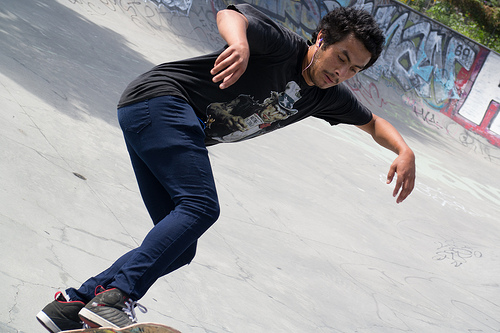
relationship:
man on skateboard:
[38, 4, 416, 332] [62, 322, 184, 331]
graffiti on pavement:
[154, 0, 499, 146] [3, 0, 496, 332]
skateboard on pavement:
[62, 322, 184, 331] [3, 0, 496, 332]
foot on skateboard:
[36, 286, 85, 332] [62, 322, 184, 331]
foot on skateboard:
[36, 289, 85, 330] [62, 322, 184, 331]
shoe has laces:
[79, 289, 135, 332] [122, 299, 146, 318]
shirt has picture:
[118, 3, 371, 145] [203, 79, 304, 144]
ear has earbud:
[312, 26, 326, 47] [317, 37, 324, 48]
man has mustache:
[38, 4, 416, 332] [324, 68, 339, 83]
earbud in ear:
[317, 37, 324, 48] [312, 26, 326, 47]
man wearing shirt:
[38, 4, 416, 332] [118, 3, 371, 145]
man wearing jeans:
[38, 4, 416, 332] [66, 97, 219, 310]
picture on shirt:
[203, 79, 304, 144] [118, 3, 371, 145]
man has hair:
[38, 4, 416, 332] [313, 6, 384, 72]